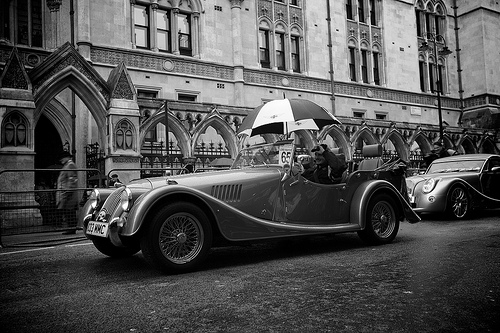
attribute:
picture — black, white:
[0, 0, 499, 332]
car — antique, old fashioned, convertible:
[75, 142, 421, 274]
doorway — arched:
[35, 114, 63, 195]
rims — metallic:
[157, 212, 204, 265]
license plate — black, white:
[84, 220, 111, 238]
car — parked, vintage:
[406, 154, 499, 221]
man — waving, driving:
[303, 145, 346, 185]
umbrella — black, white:
[235, 93, 343, 143]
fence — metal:
[81, 137, 425, 208]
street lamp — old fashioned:
[419, 32, 451, 139]